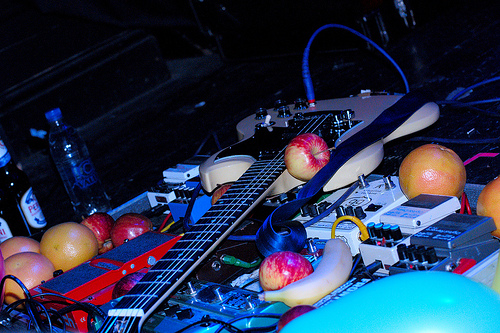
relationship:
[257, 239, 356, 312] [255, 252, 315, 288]
banana and apple